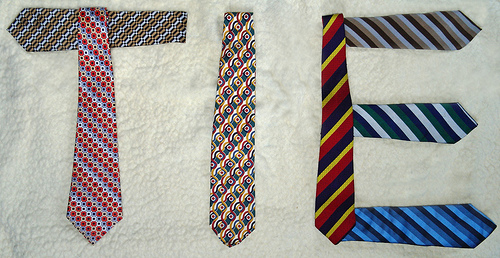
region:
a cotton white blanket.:
[132, 81, 187, 231]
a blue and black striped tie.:
[361, 200, 497, 252]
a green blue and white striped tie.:
[347, 89, 474, 151]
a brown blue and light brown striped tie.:
[342, 5, 484, 57]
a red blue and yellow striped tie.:
[311, 12, 360, 245]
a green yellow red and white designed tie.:
[205, 5, 267, 247]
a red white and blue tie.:
[56, 0, 135, 251]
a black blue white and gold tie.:
[3, 5, 197, 57]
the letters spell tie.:
[0, 0, 498, 256]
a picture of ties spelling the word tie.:
[2, 3, 497, 254]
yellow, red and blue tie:
[318, 15, 350, 232]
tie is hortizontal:
[361, 214, 492, 250]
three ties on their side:
[351, 33, 491, 247]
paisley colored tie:
[221, 6, 252, 248]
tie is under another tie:
[13, 10, 183, 41]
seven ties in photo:
[18, 15, 483, 257]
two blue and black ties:
[358, 103, 497, 250]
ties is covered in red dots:
[76, 9, 113, 235]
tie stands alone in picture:
[216, 12, 253, 252]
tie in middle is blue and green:
[354, 98, 486, 141]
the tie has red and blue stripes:
[322, 49, 358, 236]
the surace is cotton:
[274, 98, 304, 253]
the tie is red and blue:
[76, 63, 131, 244]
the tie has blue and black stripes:
[371, 188, 499, 250]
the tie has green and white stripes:
[361, 100, 475, 150]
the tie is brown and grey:
[353, 12, 464, 57]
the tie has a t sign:
[11, 5, 201, 257]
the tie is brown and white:
[11, 8, 195, 52]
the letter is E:
[296, 8, 482, 255]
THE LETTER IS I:
[212, 12, 272, 256]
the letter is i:
[219, 10, 283, 255]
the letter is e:
[326, 10, 489, 255]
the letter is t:
[11, 7, 186, 257]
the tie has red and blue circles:
[74, 68, 131, 232]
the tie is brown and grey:
[128, 20, 194, 47]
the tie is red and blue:
[210, 108, 254, 202]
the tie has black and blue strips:
[362, 195, 475, 255]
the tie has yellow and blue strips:
[319, 90, 384, 257]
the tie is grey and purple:
[343, 13, 476, 50]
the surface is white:
[150, 87, 200, 214]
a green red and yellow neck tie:
[209, 10, 256, 246]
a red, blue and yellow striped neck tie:
[315, 10, 353, 242]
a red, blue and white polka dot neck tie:
[65, 5, 120, 240]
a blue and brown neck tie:
[346, 6, 477, 46]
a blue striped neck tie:
[355, 201, 492, 246]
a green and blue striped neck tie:
[352, 100, 473, 140]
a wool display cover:
[255, 0, 310, 255]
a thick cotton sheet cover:
[123, 45, 210, 256]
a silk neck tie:
[65, 46, 120, 242]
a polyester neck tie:
[315, 12, 356, 244]